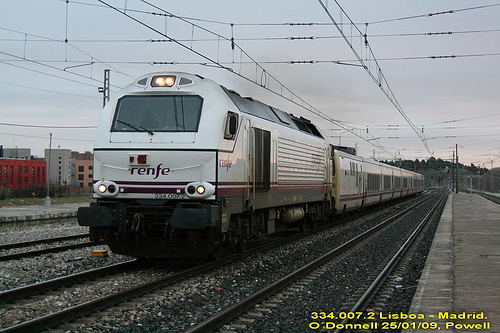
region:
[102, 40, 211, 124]
two small lit headlights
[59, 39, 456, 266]
long white train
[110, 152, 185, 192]
written label on the train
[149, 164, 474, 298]
steel train tracks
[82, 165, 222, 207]
set of headlights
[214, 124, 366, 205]
red stripes on white train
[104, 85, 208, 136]
large rectangular windsheild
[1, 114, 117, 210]
varied buildings along the tracks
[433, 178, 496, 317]
cement walk beside the track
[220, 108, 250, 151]
small rear view mirror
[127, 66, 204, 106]
train lights are on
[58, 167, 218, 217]
outer headlights are on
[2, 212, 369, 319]
3 rows of tracks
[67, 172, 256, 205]
burgundy lines on the train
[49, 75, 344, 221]
the train is silver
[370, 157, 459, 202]
red lights in the distance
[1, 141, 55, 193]
red building to the left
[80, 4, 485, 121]
wires above the train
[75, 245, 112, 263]
an orange object next to the train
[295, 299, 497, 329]
yellow writing at the bottom of screen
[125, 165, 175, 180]
burgundy print on the front of a white train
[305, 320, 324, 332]
yellow text reading O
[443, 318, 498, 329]
yellow text reading Powell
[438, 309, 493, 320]
yellow text reading Madrid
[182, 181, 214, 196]
two lights on the front of a train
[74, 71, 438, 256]
white train on a track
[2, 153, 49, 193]
wide large red building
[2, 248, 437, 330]
train tracks with gravel between it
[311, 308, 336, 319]
yellow text reading 334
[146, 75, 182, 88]
two lit lights on the front of the train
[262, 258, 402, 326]
rail road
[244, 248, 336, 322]
rail road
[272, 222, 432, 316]
rail road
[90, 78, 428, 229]
grey large train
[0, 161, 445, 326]
rails of a train station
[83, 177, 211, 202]
two front lights in a grey large train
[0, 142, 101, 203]
three buildings in the left side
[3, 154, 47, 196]
red small building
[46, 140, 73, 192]
grey small building with a lot of windows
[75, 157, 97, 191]
buildin of bricks with six windows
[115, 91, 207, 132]
windshield of a grey large train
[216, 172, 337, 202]
brown line og a large grey train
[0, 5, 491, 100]
electrical wires above the grey large train